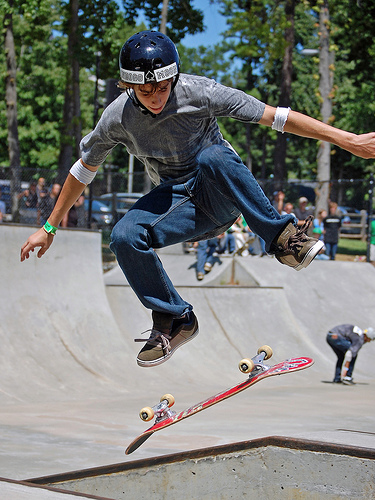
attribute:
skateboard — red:
[113, 344, 312, 458]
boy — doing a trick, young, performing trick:
[16, 30, 373, 366]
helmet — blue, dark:
[112, 28, 181, 86]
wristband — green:
[41, 217, 61, 240]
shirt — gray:
[81, 71, 267, 186]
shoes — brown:
[130, 217, 327, 372]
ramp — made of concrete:
[0, 226, 371, 499]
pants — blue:
[106, 143, 296, 318]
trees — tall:
[2, 1, 374, 215]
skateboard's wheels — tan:
[134, 337, 274, 425]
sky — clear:
[53, 5, 306, 95]